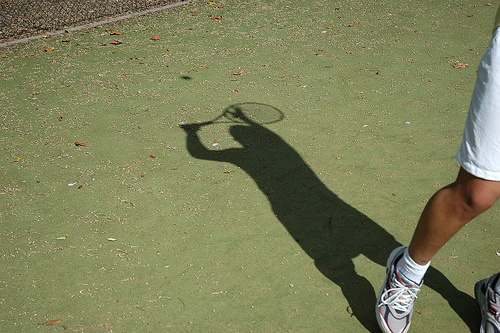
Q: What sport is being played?
A: Tennis.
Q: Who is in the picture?
A: A tennis player.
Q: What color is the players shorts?
A: White.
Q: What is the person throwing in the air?
A: Tennis ball.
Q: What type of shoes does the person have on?
A: Tennis shoes.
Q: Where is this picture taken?
A: Tennis court.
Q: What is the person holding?
A: A racket.